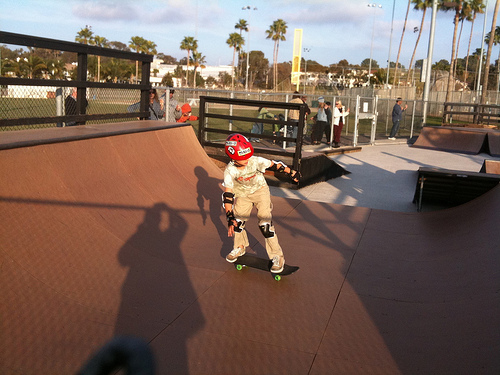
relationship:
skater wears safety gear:
[191, 136, 295, 302] [217, 166, 277, 241]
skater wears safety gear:
[219, 134, 302, 274] [217, 166, 277, 241]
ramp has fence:
[7, 97, 204, 266] [0, 31, 154, 131]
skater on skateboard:
[219, 134, 302, 274] [241, 241, 296, 282]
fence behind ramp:
[151, 88, 445, 132] [7, 97, 204, 266]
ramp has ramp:
[7, 97, 204, 266] [0, 122, 224, 327]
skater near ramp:
[219, 134, 302, 274] [7, 97, 204, 266]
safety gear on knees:
[217, 166, 277, 241] [213, 210, 270, 250]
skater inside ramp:
[219, 134, 302, 274] [7, 97, 204, 266]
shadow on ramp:
[102, 155, 190, 363] [7, 97, 204, 266]